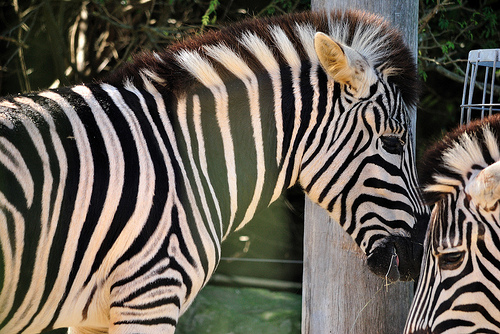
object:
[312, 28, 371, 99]
ear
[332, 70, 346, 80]
fur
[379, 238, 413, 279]
mouth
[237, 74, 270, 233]
stipe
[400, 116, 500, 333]
zebra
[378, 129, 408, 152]
eyes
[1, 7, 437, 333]
animal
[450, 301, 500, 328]
stripe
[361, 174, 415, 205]
stripe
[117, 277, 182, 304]
black stripe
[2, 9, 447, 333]
zebra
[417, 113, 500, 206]
mane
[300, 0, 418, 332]
pole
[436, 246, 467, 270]
eye